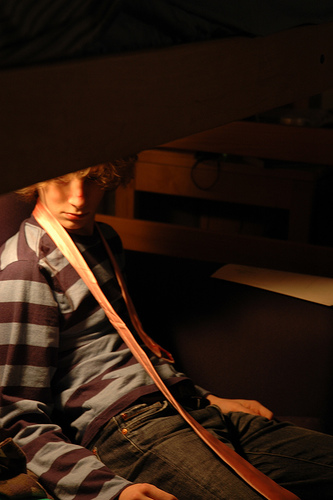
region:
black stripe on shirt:
[1, 302, 59, 327]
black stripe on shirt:
[2, 260, 47, 283]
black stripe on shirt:
[1, 343, 57, 365]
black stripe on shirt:
[2, 385, 49, 405]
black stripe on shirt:
[1, 413, 47, 439]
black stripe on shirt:
[14, 432, 64, 464]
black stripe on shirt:
[36, 447, 88, 488]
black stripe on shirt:
[66, 466, 111, 498]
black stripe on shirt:
[18, 221, 39, 262]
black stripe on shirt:
[36, 232, 57, 263]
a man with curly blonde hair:
[16, 152, 140, 228]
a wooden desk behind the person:
[142, 150, 332, 232]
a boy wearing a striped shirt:
[1, 158, 331, 496]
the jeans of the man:
[92, 390, 332, 496]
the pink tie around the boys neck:
[28, 200, 299, 498]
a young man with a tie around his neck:
[14, 149, 307, 499]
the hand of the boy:
[202, 392, 271, 417]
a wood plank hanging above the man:
[3, 23, 329, 189]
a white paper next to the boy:
[210, 258, 332, 305]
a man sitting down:
[0, 158, 322, 499]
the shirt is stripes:
[1, 212, 192, 498]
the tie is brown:
[51, 216, 186, 444]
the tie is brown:
[36, 236, 143, 371]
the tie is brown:
[74, 268, 148, 354]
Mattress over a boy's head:
[1, 1, 332, 192]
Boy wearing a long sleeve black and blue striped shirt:
[1, 211, 238, 491]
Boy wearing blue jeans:
[74, 385, 327, 496]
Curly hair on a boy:
[9, 155, 133, 189]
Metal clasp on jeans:
[120, 428, 129, 435]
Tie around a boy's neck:
[22, 197, 185, 371]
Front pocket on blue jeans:
[113, 398, 173, 432]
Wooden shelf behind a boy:
[73, 117, 331, 278]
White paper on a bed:
[207, 258, 332, 305]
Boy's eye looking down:
[85, 173, 102, 184]